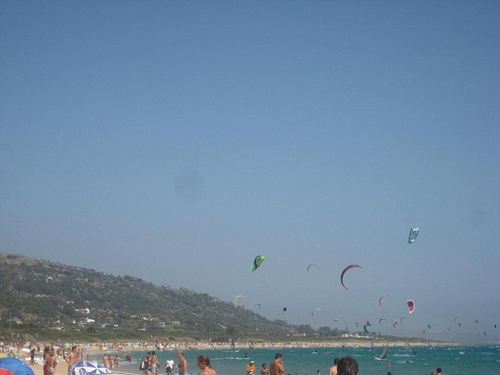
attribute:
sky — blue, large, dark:
[0, 0, 499, 347]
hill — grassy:
[0, 254, 421, 341]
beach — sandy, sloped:
[2, 342, 460, 374]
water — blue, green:
[84, 347, 500, 373]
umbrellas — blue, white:
[0, 355, 111, 374]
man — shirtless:
[271, 355, 283, 375]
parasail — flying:
[405, 299, 418, 315]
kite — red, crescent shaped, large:
[341, 262, 363, 292]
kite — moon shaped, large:
[340, 261, 363, 289]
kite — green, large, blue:
[248, 256, 266, 276]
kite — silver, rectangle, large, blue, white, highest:
[408, 227, 421, 247]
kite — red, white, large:
[406, 301, 417, 317]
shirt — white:
[166, 359, 175, 370]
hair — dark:
[339, 358, 361, 374]